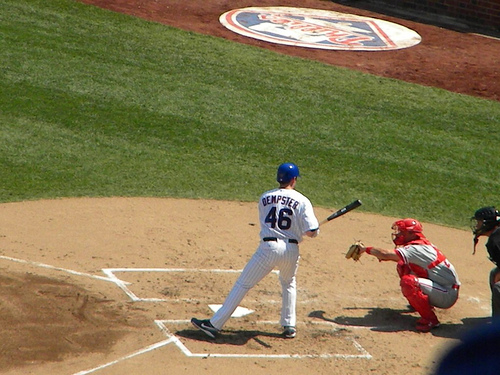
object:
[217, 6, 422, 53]
logo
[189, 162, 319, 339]
batter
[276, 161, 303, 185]
helmet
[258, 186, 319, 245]
jersey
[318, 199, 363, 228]
bat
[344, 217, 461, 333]
catcher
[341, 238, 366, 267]
mitt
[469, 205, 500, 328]
umpire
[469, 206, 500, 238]
hat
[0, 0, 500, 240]
grass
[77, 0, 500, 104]
dirt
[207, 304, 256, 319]
plate